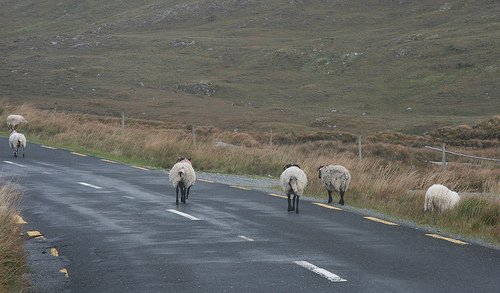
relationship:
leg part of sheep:
[172, 183, 182, 207] [164, 153, 199, 208]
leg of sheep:
[174, 185, 179, 205] [165, 153, 197, 204]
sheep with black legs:
[280, 163, 308, 214] [283, 189, 305, 212]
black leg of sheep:
[287, 194, 292, 212] [266, 136, 326, 229]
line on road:
[165, 208, 201, 221] [0, 135, 498, 290]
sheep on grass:
[423, 183, 462, 212] [356, 150, 420, 210]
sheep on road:
[2, 112, 31, 159] [0, 135, 498, 290]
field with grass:
[34, 27, 452, 256] [240, 49, 432, 122]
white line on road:
[2, 159, 23, 167] [0, 135, 498, 290]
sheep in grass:
[417, 179, 466, 234] [56, 116, 488, 211]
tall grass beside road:
[291, 144, 498, 239] [0, 135, 498, 290]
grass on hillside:
[0, 0, 499, 145] [1, 0, 498, 136]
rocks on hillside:
[10, 0, 459, 120] [1, 0, 497, 244]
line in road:
[167, 201, 199, 227] [26, 211, 391, 290]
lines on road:
[306, 189, 498, 281] [14, 104, 472, 286]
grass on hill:
[232, 79, 282, 107] [169, 24, 389, 110]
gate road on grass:
[338, 135, 498, 175] [2, 1, 498, 243]